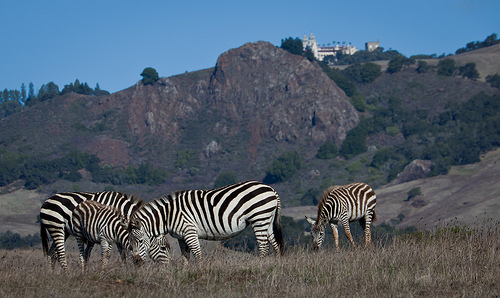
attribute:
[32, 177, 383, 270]
zebras — young , adult 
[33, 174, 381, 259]
zebra — adult , young 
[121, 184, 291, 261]
zebra —  bent neck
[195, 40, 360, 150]
boulder — red round , gray 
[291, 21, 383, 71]
building — white  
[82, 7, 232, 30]
sky — clear blue 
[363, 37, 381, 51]
building — boxes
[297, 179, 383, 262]
zebra — black, white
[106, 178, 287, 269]
zebra — white, black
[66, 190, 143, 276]
zebra — black, white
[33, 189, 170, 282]
zebra — white, black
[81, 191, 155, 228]
zebra — black, white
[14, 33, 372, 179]
mountain — stone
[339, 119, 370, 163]
bush — small, green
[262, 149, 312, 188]
bush — green, small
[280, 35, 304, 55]
bush — small, green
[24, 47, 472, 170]
hill — green, small